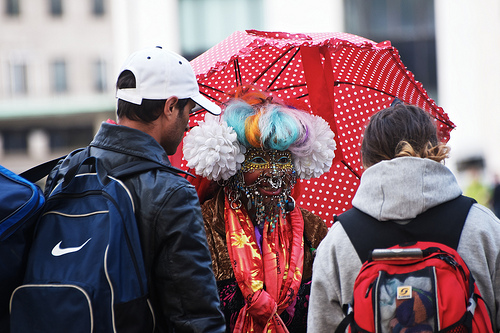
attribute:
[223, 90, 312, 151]
wig — orange, blue, purple, pur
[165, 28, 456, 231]
umbrella — red, white, polka dotted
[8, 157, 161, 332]
backpack — blue, white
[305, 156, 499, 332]
hoodie — gray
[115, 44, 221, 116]
cap — white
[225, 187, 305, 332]
scarf — red, yellow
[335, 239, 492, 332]
bag — red, black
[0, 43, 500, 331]
three people — standing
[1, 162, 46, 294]
duffle bag — blue